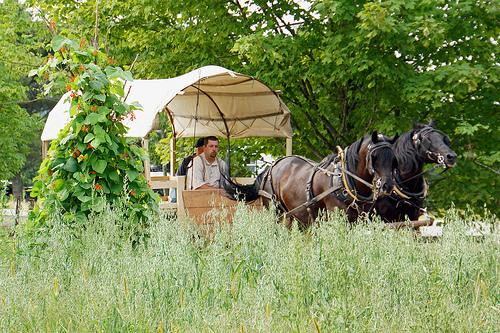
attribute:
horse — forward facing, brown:
[220, 128, 399, 230]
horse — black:
[375, 119, 459, 221]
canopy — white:
[41, 64, 295, 147]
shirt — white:
[188, 152, 231, 189]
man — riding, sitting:
[170, 135, 208, 202]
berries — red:
[94, 182, 103, 191]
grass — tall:
[1, 195, 495, 333]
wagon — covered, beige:
[40, 64, 293, 225]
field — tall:
[2, 200, 500, 333]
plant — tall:
[29, 22, 160, 236]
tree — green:
[231, 1, 426, 162]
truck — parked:
[420, 212, 494, 241]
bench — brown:
[175, 186, 266, 222]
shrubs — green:
[431, 167, 500, 217]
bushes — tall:
[2, 191, 499, 331]